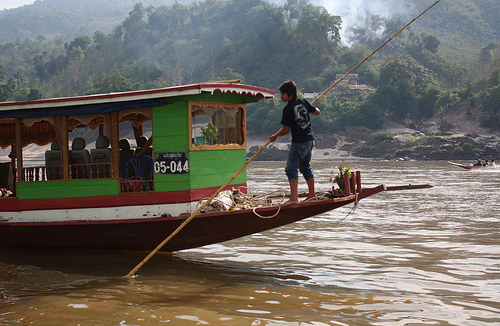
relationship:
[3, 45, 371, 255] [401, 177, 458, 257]
boat in water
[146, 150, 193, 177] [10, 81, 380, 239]
numbers on boat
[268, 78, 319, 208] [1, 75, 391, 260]
boy on boat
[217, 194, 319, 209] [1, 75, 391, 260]
space for standing on boat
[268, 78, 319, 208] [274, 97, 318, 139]
boy wearing tee shirt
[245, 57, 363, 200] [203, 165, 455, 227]
boy standing on boat deck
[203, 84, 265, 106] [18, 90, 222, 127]
trim on roof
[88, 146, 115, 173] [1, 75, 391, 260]
seat on boat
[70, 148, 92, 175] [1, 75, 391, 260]
seat on boat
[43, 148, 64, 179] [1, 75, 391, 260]
seat on boat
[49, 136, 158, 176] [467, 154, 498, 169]
people on people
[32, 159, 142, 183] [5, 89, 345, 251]
seating inside boat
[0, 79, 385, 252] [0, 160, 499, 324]
boat in water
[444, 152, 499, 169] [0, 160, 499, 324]
boat in water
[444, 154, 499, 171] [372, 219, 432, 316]
boat in water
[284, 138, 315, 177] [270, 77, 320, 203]
pants on man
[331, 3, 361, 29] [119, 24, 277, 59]
smoke in trees